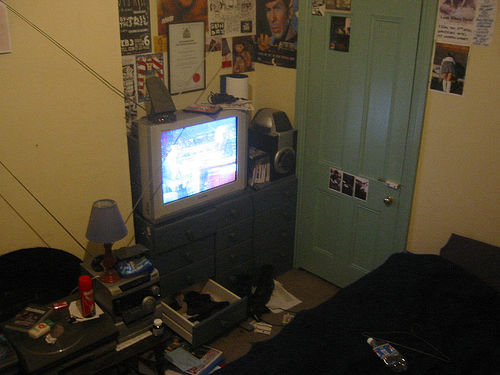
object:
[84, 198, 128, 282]
lamp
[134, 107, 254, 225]
television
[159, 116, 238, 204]
screen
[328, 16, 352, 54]
paper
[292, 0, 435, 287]
door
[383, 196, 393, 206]
knob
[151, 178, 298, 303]
bureau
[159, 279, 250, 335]
drawer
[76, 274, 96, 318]
can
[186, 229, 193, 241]
knob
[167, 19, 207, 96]
document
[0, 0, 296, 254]
wall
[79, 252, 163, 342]
stereo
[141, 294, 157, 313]
knobs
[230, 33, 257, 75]
pictures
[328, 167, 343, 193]
pictures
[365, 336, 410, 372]
bottle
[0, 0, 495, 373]
bedroom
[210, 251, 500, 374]
blanket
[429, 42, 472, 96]
picture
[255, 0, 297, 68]
poster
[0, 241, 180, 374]
entertainment center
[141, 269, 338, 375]
floor